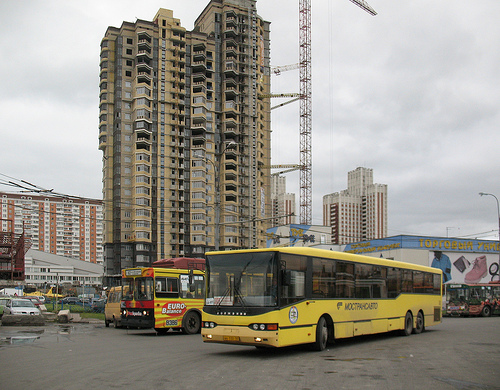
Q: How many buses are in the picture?
A: Two.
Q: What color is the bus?
A: Yellow.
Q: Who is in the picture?
A: No one.